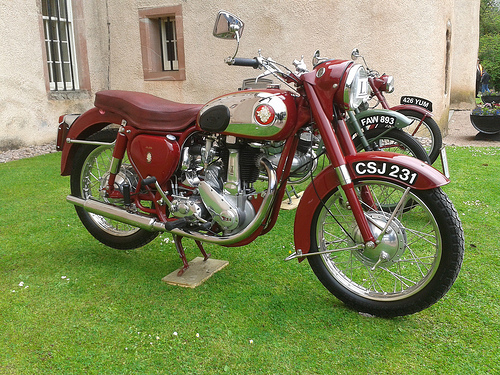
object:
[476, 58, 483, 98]
man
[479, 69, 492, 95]
man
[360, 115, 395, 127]
faw893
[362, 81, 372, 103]
headlight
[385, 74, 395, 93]
headlight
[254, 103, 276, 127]
circle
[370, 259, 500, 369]
grass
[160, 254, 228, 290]
board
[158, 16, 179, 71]
bars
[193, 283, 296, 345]
grass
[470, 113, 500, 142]
pots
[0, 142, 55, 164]
gravel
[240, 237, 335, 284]
lawn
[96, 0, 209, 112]
wall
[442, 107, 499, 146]
ground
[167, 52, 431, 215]
bike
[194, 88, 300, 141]
gas tank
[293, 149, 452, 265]
fender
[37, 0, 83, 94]
window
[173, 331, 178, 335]
flower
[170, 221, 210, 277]
kickstand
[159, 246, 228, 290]
wood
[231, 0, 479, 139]
wall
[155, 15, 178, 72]
window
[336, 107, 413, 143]
gray fender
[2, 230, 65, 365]
grass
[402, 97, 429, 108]
426yum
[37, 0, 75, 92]
bars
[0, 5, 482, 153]
building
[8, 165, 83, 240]
lawn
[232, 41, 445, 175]
motorbike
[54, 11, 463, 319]
motorbike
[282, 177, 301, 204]
kickstand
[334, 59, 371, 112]
headlamp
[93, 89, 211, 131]
seat